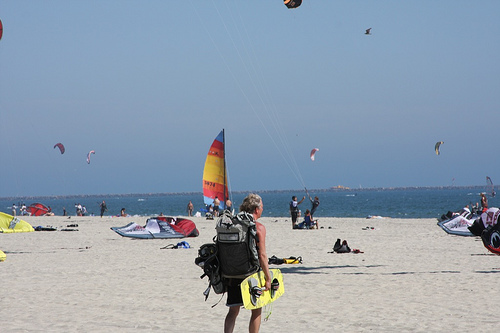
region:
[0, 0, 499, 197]
a large patch of blue sky in the background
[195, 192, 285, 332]
a man on the beach holding a wakeboard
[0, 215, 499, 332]
the sandy ground of the beach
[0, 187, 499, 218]
a large body of dark blue water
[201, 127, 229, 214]
a vehicle with a sail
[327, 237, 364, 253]
a small group of items on the sand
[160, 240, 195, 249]
a small object on the sand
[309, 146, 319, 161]
a parasail in the sky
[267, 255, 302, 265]
a bag left on the beach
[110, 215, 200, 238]
a small personal water vehicle on the beach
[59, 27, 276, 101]
A clear blue sky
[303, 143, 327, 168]
A big white kite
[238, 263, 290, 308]
A yellow snow board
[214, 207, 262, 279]
A big black backpack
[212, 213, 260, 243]
A small grey patch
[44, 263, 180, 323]
A massive grey beach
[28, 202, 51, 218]
A big red patch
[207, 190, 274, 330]
A tall white man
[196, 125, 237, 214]
A big multi colored yatcht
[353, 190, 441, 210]
A wavy blue sea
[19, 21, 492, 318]
a clear day at the beach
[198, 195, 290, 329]
the boy is carrying three backpacks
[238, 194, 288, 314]
the man has a board under his arm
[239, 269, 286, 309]
the board is yellow with black foot holders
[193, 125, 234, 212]
a sailboat is on the beach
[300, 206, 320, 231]
a person is sitting in a sand chair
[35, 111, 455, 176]
kiteboarder's kites are in the air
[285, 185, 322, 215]
two boys have harnesses on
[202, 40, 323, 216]
the boy is holding lines to the kite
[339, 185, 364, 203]
a kiteboarder skimming the water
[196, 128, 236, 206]
Multicolored sail near ocean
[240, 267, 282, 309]
Yellow water board in man's hand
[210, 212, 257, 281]
Gray and black backpack on man's back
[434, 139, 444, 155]
Parasail in blue sky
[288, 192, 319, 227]
People holding ropes on beach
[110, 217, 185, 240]
flat sail on sand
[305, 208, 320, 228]
Person in chair on beach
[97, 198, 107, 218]
Person running on beach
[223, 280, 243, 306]
Black shorts with white trim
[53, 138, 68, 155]
Red parasail in air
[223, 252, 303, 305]
Man holding a water board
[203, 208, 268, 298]
Man wearing a backpack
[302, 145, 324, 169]
pink kite in the sky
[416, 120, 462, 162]
Green kite in the sky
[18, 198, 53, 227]
Red kite on the ground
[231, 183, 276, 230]
Man with gray hair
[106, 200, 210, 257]
Jet ski on the beach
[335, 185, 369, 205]
Boat on the water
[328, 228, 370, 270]
People sitting on the beach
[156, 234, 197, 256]
Towel on the sand